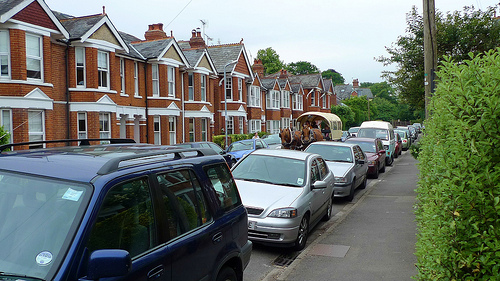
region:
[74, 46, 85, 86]
building has a window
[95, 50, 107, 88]
building has a window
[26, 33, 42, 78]
building has a window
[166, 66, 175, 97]
building has a window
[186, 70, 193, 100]
building has a window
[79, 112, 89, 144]
building has a window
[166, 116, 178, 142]
building has a window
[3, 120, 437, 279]
cars parked next to the side walk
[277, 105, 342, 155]
Two horses pulling a wagon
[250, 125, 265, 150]
person standing in the street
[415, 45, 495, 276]
Healthy looking green bush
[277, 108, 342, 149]
Brown horses pulling a wagon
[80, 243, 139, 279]
Blue mirror on the side of the car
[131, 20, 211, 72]
Chimneys on house roofs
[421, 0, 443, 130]
Wooden pole on the side of the walk way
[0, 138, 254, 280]
A blue parked suv.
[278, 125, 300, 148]
Brown horse with it's head down lower.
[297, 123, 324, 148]
Brown horse wtih it's head up higher.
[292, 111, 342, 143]
A yellow arched carriage.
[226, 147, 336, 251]
A white car parked behind a blue suv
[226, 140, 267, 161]
A blue parked car near a wagon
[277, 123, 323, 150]
Two brown horses pulling a wagon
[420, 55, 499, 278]
A bright green bush near a blue suv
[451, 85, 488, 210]
green bush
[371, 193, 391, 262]
clean gray sidewalk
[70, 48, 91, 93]
window in the second floor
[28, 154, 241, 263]
blue suv parked on street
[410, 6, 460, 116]
brown unity pole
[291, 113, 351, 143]
brown horse and carriage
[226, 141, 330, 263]
white car parked on the street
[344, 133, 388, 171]
red car parked on the street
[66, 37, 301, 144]
brick houses in a row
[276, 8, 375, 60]
overcast skies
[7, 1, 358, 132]
A row of houses.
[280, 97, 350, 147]
A horse and buggy.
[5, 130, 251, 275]
A blue SUV.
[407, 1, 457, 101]
A utility pole.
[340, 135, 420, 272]
The sidewalk.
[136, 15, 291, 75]
Chimneys on the roofs of the houses.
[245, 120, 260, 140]
A woman walking on the sidewalk.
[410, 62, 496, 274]
A large hedge.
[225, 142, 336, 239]
A silver sedan parked parallel to the sidewalk.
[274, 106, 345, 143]
Two horses pulling a carriage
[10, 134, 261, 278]
Blue SUV parked along the street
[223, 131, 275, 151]
Man getting out of a blue car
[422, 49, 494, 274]
Hedge along the street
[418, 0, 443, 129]
Telephone pole along the street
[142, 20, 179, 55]
Chimney on top of a roof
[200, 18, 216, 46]
Televison Antennas of the roof of a house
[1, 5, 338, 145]
Row of city brick houses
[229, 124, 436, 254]
Cars Parked along the street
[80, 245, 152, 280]
Mirro on the side of SUV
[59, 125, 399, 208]
Cars are parked by the sidewalk.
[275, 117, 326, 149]
Horses are in the middle of the road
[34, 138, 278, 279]
The truck is blue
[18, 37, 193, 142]
The house are made out of brick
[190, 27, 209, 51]
The chimney is on top of the roof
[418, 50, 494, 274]
The bushes are green.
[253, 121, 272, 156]
A person is looking at the horse buggy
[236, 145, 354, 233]
A silver car is parked behind the blue truck